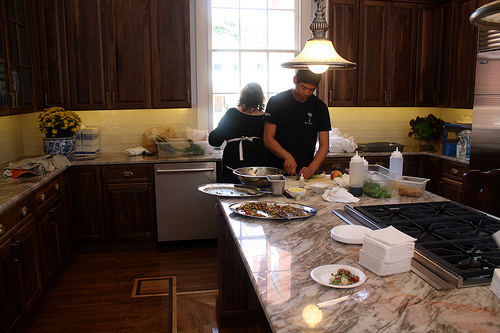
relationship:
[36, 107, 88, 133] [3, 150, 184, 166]
flower on counter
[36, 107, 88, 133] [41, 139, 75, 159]
flower inside pot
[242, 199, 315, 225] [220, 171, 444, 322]
tray on counter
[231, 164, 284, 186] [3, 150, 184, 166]
basin on counter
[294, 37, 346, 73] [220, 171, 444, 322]
light above counter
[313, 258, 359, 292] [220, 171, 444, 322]
plate on top of counter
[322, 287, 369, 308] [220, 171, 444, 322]
fork on top of counter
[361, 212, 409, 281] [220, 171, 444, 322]
napkins on top of counter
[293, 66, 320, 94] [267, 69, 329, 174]
head of man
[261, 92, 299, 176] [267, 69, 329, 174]
arm of man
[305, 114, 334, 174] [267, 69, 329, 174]
arm of man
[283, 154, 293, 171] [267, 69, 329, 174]
hand of man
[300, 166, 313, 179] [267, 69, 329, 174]
hand of man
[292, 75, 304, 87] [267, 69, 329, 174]
ear of man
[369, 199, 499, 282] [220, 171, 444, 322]
stove on counter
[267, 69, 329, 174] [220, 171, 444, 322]
man working at counter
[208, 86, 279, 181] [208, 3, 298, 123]
woman working in front of window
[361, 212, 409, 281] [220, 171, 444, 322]
napkins on counter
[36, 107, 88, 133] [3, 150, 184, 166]
flower on top of counter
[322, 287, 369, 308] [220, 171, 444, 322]
fork on counter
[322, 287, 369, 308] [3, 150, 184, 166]
fork on top of counter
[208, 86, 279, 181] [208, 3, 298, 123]
woman in front of window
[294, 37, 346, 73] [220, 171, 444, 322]
light hanging above counter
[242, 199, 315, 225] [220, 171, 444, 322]
tray on top of counter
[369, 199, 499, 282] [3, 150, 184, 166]
stove on counter